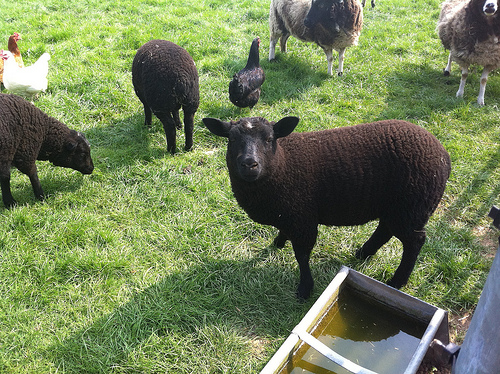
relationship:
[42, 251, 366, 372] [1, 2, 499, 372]
shadow on grass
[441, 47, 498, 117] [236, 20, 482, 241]
legs on animals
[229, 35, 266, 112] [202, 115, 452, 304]
chicken around black sheep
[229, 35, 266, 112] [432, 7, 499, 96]
chicken around sheep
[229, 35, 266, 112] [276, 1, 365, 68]
chicken around sheep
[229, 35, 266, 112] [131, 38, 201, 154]
chicken around black sheep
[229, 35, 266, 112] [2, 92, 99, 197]
chicken around sheep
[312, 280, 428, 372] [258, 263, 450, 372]
water in bin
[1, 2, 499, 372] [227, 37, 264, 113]
grass under animals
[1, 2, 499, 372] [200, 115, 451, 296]
grass under animals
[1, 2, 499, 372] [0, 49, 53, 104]
grass under animals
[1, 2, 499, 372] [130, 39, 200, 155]
grass under animals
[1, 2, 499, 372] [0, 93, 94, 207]
grass under animals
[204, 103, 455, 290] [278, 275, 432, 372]
black sheep near water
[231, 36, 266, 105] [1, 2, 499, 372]
chicken on grass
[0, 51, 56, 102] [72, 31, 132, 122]
chicken on grass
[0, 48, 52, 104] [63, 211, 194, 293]
chicken on grass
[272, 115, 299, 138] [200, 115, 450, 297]
ear on black sheep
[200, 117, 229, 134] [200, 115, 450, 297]
ear on black sheep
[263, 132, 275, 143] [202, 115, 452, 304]
eye on black sheep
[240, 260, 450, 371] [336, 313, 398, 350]
bin filled with water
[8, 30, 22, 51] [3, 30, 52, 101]
head of a chicken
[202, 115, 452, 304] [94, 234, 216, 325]
black sheep grazing on grass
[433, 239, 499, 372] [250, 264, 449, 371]
trough attached to fence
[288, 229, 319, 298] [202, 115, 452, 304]
leg of black sheep